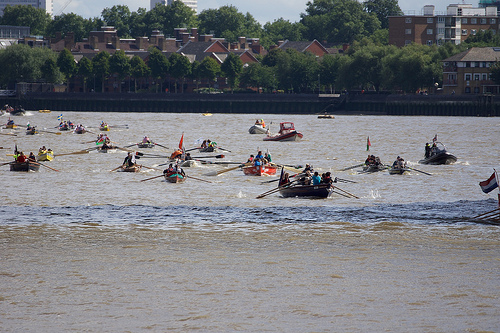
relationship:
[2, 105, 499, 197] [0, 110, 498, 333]
boats on water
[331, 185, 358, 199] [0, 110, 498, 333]
paddles in water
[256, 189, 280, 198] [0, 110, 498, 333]
paddles in water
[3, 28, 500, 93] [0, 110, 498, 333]
trees by water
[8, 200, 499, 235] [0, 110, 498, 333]
ripples in water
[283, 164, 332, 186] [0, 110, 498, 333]
people on water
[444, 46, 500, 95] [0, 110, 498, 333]
building beside water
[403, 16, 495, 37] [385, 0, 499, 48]
windows on building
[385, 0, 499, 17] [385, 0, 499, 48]
roof on building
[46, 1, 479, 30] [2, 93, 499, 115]
sky above land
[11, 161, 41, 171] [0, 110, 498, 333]
boat in water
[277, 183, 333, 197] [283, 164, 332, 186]
boat full of people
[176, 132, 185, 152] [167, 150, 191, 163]
flag on boat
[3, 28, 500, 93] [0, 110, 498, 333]
trees beside water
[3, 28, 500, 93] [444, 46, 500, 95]
trees surrounding building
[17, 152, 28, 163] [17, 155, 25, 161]
person wearing a shirt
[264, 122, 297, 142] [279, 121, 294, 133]
boat has a cabin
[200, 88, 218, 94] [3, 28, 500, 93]
car parked under trees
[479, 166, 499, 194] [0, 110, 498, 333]
flag in water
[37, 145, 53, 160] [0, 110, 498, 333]
boat on water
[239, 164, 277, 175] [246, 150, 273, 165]
boat full of people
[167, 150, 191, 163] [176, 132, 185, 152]
boat has a flag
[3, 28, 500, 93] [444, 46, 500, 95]
trees in front of building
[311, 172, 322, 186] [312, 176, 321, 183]
people wearing a shirt